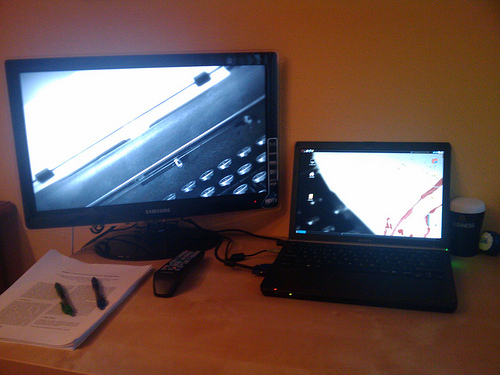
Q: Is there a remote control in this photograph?
A: Yes, there is a remote control.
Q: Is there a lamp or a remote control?
A: Yes, there is a remote control.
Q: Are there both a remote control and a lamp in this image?
A: No, there is a remote control but no lamps.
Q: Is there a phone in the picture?
A: No, there are no phones.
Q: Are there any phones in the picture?
A: No, there are no phones.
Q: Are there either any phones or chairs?
A: No, there are no phones or chairs.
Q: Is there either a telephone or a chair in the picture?
A: No, there are no phones or chairs.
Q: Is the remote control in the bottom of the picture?
A: Yes, the remote control is in the bottom of the image.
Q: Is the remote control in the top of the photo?
A: No, the remote control is in the bottom of the image.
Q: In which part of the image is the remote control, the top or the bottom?
A: The remote control is in the bottom of the image.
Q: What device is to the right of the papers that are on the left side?
A: The device is a remote control.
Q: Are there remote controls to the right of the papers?
A: Yes, there is a remote control to the right of the papers.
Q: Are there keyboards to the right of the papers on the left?
A: No, there is a remote control to the right of the papers.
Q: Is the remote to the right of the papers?
A: Yes, the remote is to the right of the papers.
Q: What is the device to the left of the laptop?
A: The device is a remote control.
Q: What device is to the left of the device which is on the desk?
A: The device is a remote control.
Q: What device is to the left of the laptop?
A: The device is a remote control.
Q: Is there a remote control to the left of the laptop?
A: Yes, there is a remote control to the left of the laptop.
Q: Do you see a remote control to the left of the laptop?
A: Yes, there is a remote control to the left of the laptop.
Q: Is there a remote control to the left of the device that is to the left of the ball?
A: Yes, there is a remote control to the left of the laptop.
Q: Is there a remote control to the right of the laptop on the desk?
A: No, the remote control is to the left of the laptop.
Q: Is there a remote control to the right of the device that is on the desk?
A: No, the remote control is to the left of the laptop.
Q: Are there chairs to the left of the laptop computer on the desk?
A: No, there is a remote control to the left of the laptop computer.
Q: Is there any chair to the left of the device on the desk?
A: No, there is a remote control to the left of the laptop computer.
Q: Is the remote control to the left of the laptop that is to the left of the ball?
A: Yes, the remote control is to the left of the laptop computer.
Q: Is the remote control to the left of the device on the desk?
A: Yes, the remote control is to the left of the laptop computer.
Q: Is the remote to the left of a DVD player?
A: No, the remote is to the left of the laptop computer.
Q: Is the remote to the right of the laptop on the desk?
A: No, the remote is to the left of the laptop computer.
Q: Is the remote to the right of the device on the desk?
A: No, the remote is to the left of the laptop computer.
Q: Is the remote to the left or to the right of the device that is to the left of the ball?
A: The remote is to the left of the laptop computer.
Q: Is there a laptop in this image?
A: Yes, there is a laptop.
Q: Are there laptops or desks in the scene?
A: Yes, there is a laptop.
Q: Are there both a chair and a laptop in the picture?
A: No, there is a laptop but no chairs.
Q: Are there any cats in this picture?
A: No, there are no cats.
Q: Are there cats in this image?
A: No, there are no cats.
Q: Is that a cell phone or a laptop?
A: That is a laptop.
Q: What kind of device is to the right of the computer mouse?
A: The device is a laptop.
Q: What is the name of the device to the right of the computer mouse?
A: The device is a laptop.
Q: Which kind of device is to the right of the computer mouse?
A: The device is a laptop.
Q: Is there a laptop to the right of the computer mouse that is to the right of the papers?
A: Yes, there is a laptop to the right of the computer mouse.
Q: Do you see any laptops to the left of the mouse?
A: No, the laptop is to the right of the mouse.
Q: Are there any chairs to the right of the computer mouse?
A: No, there is a laptop to the right of the computer mouse.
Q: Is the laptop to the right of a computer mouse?
A: Yes, the laptop is to the right of a computer mouse.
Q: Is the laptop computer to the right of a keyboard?
A: No, the laptop computer is to the right of a computer mouse.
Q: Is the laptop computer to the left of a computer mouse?
A: No, the laptop computer is to the right of a computer mouse.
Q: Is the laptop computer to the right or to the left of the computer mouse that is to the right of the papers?
A: The laptop computer is to the right of the computer mouse.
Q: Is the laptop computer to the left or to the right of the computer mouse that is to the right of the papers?
A: The laptop computer is to the right of the computer mouse.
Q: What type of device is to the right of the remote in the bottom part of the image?
A: The device is a laptop.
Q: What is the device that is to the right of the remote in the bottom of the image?
A: The device is a laptop.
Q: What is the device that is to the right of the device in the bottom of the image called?
A: The device is a laptop.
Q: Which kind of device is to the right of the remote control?
A: The device is a laptop.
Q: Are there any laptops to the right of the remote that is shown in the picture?
A: Yes, there is a laptop to the right of the remote.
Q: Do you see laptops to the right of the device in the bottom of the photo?
A: Yes, there is a laptop to the right of the remote.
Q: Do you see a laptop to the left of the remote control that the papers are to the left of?
A: No, the laptop is to the right of the remote control.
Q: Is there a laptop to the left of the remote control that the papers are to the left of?
A: No, the laptop is to the right of the remote control.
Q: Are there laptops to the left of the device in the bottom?
A: No, the laptop is to the right of the remote control.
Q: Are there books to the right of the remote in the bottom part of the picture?
A: No, there is a laptop to the right of the remote control.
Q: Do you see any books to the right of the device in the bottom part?
A: No, there is a laptop to the right of the remote control.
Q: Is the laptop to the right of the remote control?
A: Yes, the laptop is to the right of the remote control.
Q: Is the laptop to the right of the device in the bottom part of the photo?
A: Yes, the laptop is to the right of the remote control.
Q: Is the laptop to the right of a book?
A: No, the laptop is to the right of the remote control.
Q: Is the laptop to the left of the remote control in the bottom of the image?
A: No, the laptop is to the right of the remote control.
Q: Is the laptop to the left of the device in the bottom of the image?
A: No, the laptop is to the right of the remote control.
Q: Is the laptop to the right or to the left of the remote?
A: The laptop is to the right of the remote.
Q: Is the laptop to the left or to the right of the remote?
A: The laptop is to the right of the remote.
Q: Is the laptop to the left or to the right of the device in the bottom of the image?
A: The laptop is to the right of the remote.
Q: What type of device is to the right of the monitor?
A: The device is a laptop.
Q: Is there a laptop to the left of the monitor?
A: No, the laptop is to the right of the monitor.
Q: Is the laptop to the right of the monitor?
A: Yes, the laptop is to the right of the monitor.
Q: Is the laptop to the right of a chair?
A: No, the laptop is to the right of the monitor.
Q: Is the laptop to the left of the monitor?
A: No, the laptop is to the right of the monitor.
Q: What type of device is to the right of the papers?
A: The device is a laptop.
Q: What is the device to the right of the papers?
A: The device is a laptop.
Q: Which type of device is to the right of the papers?
A: The device is a laptop.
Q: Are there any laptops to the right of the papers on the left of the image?
A: Yes, there is a laptop to the right of the papers.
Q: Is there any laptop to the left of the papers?
A: No, the laptop is to the right of the papers.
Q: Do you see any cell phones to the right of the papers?
A: No, there is a laptop to the right of the papers.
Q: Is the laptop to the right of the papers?
A: Yes, the laptop is to the right of the papers.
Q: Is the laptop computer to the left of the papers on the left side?
A: No, the laptop computer is to the right of the papers.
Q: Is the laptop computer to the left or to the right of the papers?
A: The laptop computer is to the right of the papers.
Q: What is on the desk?
A: The laptop computer is on the desk.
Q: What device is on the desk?
A: The device is a laptop.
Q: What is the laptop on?
A: The laptop is on the desk.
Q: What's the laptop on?
A: The laptop is on the desk.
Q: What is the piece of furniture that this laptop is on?
A: The piece of furniture is a desk.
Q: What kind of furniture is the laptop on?
A: The laptop is on the desk.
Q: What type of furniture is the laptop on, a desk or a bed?
A: The laptop is on a desk.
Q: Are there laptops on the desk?
A: Yes, there is a laptop on the desk.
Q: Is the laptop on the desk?
A: Yes, the laptop is on the desk.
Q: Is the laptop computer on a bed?
A: No, the laptop computer is on the desk.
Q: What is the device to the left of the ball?
A: The device is a laptop.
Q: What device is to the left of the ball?
A: The device is a laptop.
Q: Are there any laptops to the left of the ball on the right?
A: Yes, there is a laptop to the left of the ball.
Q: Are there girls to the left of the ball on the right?
A: No, there is a laptop to the left of the ball.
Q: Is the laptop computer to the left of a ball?
A: Yes, the laptop computer is to the left of a ball.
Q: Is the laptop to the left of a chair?
A: No, the laptop is to the left of a ball.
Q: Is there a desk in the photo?
A: Yes, there is a desk.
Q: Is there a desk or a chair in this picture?
A: Yes, there is a desk.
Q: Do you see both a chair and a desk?
A: No, there is a desk but no chairs.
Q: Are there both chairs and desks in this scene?
A: No, there is a desk but no chairs.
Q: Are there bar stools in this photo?
A: No, there are no bar stools.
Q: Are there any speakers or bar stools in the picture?
A: No, there are no bar stools or speakers.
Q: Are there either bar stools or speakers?
A: No, there are no bar stools or speakers.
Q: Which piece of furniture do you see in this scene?
A: The piece of furniture is a desk.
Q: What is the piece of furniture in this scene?
A: The piece of furniture is a desk.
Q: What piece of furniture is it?
A: The piece of furniture is a desk.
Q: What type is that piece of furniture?
A: This is a desk.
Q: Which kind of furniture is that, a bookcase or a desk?
A: This is a desk.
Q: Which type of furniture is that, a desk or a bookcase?
A: This is a desk.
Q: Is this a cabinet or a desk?
A: This is a desk.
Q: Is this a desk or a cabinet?
A: This is a desk.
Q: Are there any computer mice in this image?
A: Yes, there is a computer mouse.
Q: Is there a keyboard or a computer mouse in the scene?
A: Yes, there is a computer mouse.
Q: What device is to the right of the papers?
A: The device is a computer mouse.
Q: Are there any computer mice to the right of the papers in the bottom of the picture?
A: Yes, there is a computer mouse to the right of the papers.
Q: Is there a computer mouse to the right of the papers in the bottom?
A: Yes, there is a computer mouse to the right of the papers.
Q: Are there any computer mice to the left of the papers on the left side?
A: No, the computer mouse is to the right of the papers.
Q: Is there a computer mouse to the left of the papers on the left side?
A: No, the computer mouse is to the right of the papers.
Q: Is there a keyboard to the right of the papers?
A: No, there is a computer mouse to the right of the papers.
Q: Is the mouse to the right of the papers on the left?
A: Yes, the mouse is to the right of the papers.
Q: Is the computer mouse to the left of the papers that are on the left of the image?
A: No, the computer mouse is to the right of the papers.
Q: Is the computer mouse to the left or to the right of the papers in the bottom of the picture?
A: The computer mouse is to the right of the papers.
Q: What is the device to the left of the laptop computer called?
A: The device is a computer mouse.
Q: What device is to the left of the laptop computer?
A: The device is a computer mouse.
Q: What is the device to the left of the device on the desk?
A: The device is a computer mouse.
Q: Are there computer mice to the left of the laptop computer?
A: Yes, there is a computer mouse to the left of the laptop computer.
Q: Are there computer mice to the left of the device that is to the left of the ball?
A: Yes, there is a computer mouse to the left of the laptop computer.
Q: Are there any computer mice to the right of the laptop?
A: No, the computer mouse is to the left of the laptop.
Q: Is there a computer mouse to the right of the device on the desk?
A: No, the computer mouse is to the left of the laptop.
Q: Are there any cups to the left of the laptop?
A: No, there is a computer mouse to the left of the laptop.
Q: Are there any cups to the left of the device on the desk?
A: No, there is a computer mouse to the left of the laptop.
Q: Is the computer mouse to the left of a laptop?
A: Yes, the computer mouse is to the left of a laptop.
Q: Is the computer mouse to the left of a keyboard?
A: No, the computer mouse is to the left of a laptop.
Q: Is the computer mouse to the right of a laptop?
A: No, the computer mouse is to the left of a laptop.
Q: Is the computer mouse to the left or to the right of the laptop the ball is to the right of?
A: The computer mouse is to the left of the laptop.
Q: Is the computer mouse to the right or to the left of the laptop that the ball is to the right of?
A: The computer mouse is to the left of the laptop.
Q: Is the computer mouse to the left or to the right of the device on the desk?
A: The computer mouse is to the left of the laptop.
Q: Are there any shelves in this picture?
A: No, there are no shelves.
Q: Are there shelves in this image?
A: No, there are no shelves.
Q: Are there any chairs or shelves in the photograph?
A: No, there are no shelves or chairs.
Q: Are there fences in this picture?
A: No, there are no fences.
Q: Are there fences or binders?
A: No, there are no fences or binders.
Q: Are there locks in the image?
A: No, there are no locks.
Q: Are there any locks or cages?
A: No, there are no locks or cages.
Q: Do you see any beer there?
A: Yes, there is beer.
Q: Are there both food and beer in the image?
A: No, there is beer but no food.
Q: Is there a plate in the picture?
A: No, there are no plates.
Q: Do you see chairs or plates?
A: No, there are no plates or chairs.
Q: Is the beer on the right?
A: Yes, the beer is on the right of the image.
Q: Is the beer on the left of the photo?
A: No, the beer is on the right of the image.